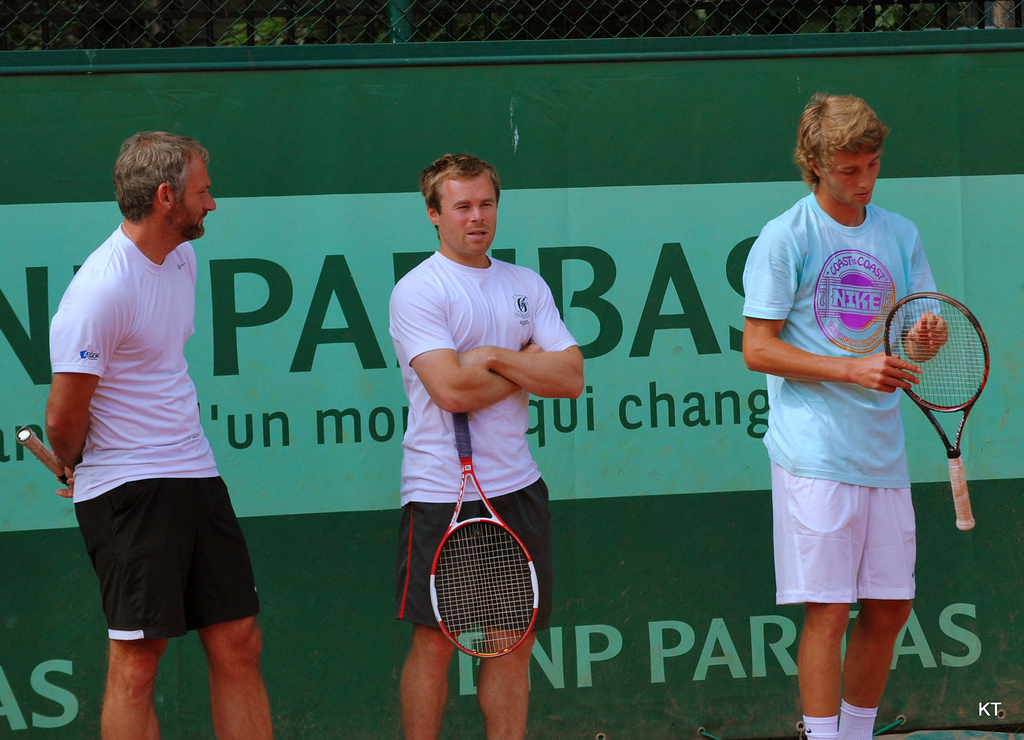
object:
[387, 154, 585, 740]
man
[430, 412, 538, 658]
racket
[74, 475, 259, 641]
shorts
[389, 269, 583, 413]
arms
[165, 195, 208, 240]
beard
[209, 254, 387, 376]
letters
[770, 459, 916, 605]
shorts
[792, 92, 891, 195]
hair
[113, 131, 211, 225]
hair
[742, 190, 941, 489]
shirt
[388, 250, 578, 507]
shirt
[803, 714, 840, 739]
socks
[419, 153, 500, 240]
hair